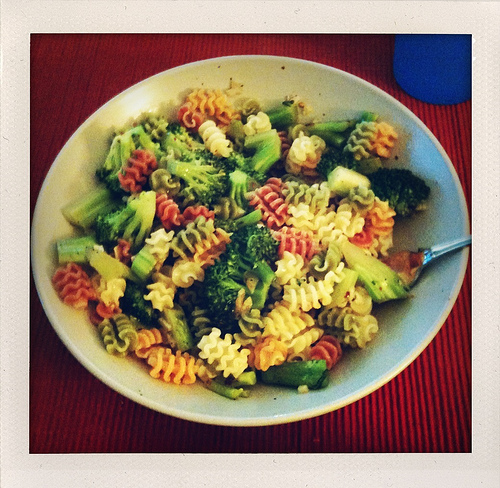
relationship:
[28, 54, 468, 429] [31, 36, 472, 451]
bowl on table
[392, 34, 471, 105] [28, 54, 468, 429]
blue cup next to bowl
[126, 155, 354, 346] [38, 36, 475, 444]
noodles are in bowl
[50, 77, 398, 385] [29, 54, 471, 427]
noodles on a bowl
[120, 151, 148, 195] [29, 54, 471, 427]
peice are on bowl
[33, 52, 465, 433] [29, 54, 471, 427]
peice are on bowl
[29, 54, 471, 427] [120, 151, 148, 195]
bowl are on peice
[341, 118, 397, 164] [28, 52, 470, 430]
piece on a plate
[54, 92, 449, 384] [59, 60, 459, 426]
broccoli in a bowl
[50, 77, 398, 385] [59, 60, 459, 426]
noodles in a bowl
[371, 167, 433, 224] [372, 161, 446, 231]
broccoli has piece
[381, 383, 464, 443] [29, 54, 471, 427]
placement under bowl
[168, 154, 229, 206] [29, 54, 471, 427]
broccoli in bowl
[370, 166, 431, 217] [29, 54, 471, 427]
broccoli in bowl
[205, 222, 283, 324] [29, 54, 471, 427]
broccoli in bowl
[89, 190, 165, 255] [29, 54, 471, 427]
broccoli in bowl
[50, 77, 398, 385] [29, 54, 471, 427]
noodles in bowl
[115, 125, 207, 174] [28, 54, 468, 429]
broccoli in bowl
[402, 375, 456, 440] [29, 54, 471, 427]
stripes under bowl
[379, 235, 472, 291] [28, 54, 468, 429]
fork on bowl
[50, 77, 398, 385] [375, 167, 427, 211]
noodles with broccoli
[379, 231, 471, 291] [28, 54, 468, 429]
fork in bowl